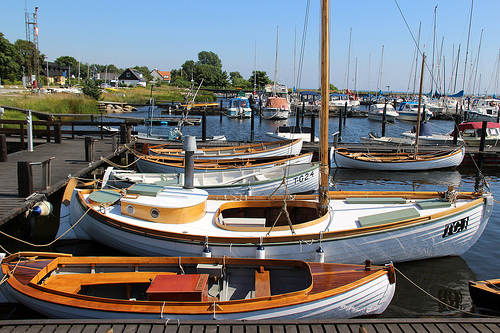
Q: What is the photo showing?
A: It is showing a harbor.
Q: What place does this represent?
A: It represents the harbor.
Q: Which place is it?
A: It is a harbor.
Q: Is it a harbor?
A: Yes, it is a harbor.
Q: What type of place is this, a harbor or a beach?
A: It is a harbor.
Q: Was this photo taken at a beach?
A: No, the picture was taken in a harbor.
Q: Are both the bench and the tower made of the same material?
A: No, the bench is made of wood and the tower is made of metal.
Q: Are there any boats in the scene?
A: Yes, there is a boat.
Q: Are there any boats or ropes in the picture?
A: Yes, there is a boat.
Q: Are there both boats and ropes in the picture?
A: Yes, there are both a boat and a rope.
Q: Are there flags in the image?
A: No, there are no flags.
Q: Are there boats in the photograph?
A: Yes, there is a boat.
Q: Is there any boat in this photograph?
A: Yes, there is a boat.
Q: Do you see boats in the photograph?
A: Yes, there is a boat.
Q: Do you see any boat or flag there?
A: Yes, there is a boat.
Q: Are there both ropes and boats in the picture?
A: Yes, there are both a boat and a rope.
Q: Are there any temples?
A: No, there are no temples.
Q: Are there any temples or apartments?
A: No, there are no temples or apartments.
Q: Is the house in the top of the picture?
A: Yes, the house is in the top of the image.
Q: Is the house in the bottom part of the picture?
A: No, the house is in the top of the image.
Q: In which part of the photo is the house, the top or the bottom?
A: The house is in the top of the image.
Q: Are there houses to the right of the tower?
A: Yes, there is a house to the right of the tower.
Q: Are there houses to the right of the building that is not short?
A: Yes, there is a house to the right of the tower.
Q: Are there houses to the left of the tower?
A: No, the house is to the right of the tower.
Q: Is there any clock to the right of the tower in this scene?
A: No, there is a house to the right of the tower.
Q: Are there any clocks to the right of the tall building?
A: No, there is a house to the right of the tower.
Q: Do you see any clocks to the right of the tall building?
A: No, there is a house to the right of the tower.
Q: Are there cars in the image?
A: No, there are no cars.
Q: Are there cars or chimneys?
A: No, there are no cars or chimneys.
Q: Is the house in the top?
A: Yes, the house is in the top of the image.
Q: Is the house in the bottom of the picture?
A: No, the house is in the top of the image.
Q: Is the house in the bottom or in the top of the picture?
A: The house is in the top of the image.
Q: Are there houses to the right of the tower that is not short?
A: Yes, there is a house to the right of the tower.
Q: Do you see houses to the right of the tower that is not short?
A: Yes, there is a house to the right of the tower.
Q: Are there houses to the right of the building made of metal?
A: Yes, there is a house to the right of the tower.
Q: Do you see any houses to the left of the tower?
A: No, the house is to the right of the tower.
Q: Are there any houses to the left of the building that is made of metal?
A: No, the house is to the right of the tower.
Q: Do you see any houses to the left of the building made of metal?
A: No, the house is to the right of the tower.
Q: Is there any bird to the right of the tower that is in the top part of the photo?
A: No, there is a house to the right of the tower.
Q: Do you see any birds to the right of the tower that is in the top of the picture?
A: No, there is a house to the right of the tower.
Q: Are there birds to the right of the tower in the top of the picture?
A: No, there is a house to the right of the tower.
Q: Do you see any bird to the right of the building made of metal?
A: No, there is a house to the right of the tower.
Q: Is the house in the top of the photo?
A: Yes, the house is in the top of the image.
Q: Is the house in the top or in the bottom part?
A: The house is in the top of the image.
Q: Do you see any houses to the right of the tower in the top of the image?
A: Yes, there is a house to the right of the tower.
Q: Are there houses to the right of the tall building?
A: Yes, there is a house to the right of the tower.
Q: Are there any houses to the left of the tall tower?
A: No, the house is to the right of the tower.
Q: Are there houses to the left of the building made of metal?
A: No, the house is to the right of the tower.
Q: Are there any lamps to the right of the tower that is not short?
A: No, there is a house to the right of the tower.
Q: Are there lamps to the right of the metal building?
A: No, there is a house to the right of the tower.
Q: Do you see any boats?
A: Yes, there is a boat.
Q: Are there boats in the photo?
A: Yes, there is a boat.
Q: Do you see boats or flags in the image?
A: Yes, there is a boat.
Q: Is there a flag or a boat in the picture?
A: Yes, there is a boat.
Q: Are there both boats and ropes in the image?
A: Yes, there are both a boat and a rope.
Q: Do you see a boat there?
A: Yes, there is a boat.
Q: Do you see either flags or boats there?
A: Yes, there is a boat.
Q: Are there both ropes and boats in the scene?
A: Yes, there are both a boat and a rope.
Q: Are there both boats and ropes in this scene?
A: Yes, there are both a boat and a rope.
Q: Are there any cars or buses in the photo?
A: No, there are no cars or buses.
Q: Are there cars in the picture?
A: No, there are no cars.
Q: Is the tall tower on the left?
A: Yes, the tower is on the left of the image.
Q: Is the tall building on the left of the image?
A: Yes, the tower is on the left of the image.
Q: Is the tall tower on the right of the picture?
A: No, the tower is on the left of the image.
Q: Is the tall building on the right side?
A: No, the tower is on the left of the image.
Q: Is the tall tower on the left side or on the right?
A: The tower is on the left of the image.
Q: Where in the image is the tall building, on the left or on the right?
A: The tower is on the left of the image.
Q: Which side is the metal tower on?
A: The tower is on the left of the image.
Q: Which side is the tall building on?
A: The tower is on the left of the image.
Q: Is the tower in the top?
A: Yes, the tower is in the top of the image.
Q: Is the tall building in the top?
A: Yes, the tower is in the top of the image.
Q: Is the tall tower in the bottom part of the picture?
A: No, the tower is in the top of the image.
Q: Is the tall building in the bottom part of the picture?
A: No, the tower is in the top of the image.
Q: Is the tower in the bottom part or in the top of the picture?
A: The tower is in the top of the image.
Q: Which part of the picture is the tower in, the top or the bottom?
A: The tower is in the top of the image.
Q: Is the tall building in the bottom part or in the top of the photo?
A: The tower is in the top of the image.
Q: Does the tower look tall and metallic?
A: Yes, the tower is tall and metallic.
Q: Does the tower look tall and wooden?
A: No, the tower is tall but metallic.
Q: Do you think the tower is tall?
A: Yes, the tower is tall.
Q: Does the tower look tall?
A: Yes, the tower is tall.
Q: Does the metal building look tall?
A: Yes, the tower is tall.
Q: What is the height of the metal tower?
A: The tower is tall.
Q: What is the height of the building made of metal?
A: The tower is tall.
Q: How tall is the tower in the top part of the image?
A: The tower is tall.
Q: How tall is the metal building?
A: The tower is tall.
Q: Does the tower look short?
A: No, the tower is tall.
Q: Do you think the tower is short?
A: No, the tower is tall.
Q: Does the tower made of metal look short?
A: No, the tower is tall.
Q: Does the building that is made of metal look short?
A: No, the tower is tall.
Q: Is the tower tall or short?
A: The tower is tall.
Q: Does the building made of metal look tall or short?
A: The tower is tall.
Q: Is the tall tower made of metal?
A: Yes, the tower is made of metal.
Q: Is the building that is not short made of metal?
A: Yes, the tower is made of metal.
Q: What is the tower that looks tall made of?
A: The tower is made of metal.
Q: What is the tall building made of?
A: The tower is made of metal.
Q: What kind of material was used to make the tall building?
A: The tower is made of metal.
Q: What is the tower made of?
A: The tower is made of metal.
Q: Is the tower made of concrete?
A: No, the tower is made of metal.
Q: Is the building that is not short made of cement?
A: No, the tower is made of metal.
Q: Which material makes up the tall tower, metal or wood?
A: The tower is made of metal.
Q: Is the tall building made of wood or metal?
A: The tower is made of metal.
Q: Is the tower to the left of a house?
A: Yes, the tower is to the left of a house.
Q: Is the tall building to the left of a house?
A: Yes, the tower is to the left of a house.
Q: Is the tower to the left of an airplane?
A: No, the tower is to the left of a house.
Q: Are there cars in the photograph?
A: No, there are no cars.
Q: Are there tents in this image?
A: No, there are no tents.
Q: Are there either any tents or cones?
A: No, there are no tents or cones.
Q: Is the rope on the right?
A: Yes, the rope is on the right of the image.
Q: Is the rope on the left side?
A: No, the rope is on the right of the image.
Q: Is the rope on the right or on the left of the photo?
A: The rope is on the right of the image.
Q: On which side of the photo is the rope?
A: The rope is on the right of the image.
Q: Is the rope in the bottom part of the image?
A: Yes, the rope is in the bottom of the image.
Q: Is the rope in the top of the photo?
A: No, the rope is in the bottom of the image.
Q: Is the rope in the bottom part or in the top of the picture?
A: The rope is in the bottom of the image.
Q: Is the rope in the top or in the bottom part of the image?
A: The rope is in the bottom of the image.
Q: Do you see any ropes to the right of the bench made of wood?
A: Yes, there is a rope to the right of the bench.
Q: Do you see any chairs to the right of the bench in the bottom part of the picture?
A: No, there is a rope to the right of the bench.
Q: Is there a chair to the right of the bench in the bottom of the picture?
A: No, there is a rope to the right of the bench.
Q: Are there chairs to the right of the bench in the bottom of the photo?
A: No, there is a rope to the right of the bench.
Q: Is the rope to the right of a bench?
A: Yes, the rope is to the right of a bench.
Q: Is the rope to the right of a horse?
A: No, the rope is to the right of a bench.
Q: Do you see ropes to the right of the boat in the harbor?
A: Yes, there is a rope to the right of the boat.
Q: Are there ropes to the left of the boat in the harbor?
A: No, the rope is to the right of the boat.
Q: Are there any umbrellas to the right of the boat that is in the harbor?
A: No, there is a rope to the right of the boat.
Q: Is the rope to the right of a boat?
A: Yes, the rope is to the right of a boat.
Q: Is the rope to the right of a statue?
A: No, the rope is to the right of a boat.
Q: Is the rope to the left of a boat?
A: No, the rope is to the right of a boat.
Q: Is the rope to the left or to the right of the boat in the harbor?
A: The rope is to the right of the boat.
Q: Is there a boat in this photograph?
A: Yes, there is a boat.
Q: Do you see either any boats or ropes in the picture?
A: Yes, there is a boat.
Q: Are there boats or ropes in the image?
A: Yes, there is a boat.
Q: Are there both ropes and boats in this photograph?
A: Yes, there are both a boat and a rope.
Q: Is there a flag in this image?
A: No, there are no flags.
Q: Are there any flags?
A: No, there are no flags.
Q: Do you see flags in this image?
A: No, there are no flags.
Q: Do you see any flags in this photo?
A: No, there are no flags.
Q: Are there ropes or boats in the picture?
A: Yes, there is a boat.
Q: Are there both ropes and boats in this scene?
A: Yes, there are both a boat and a rope.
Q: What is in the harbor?
A: The boat is in the harbor.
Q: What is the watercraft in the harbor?
A: The watercraft is a boat.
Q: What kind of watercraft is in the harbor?
A: The watercraft is a boat.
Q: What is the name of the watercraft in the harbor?
A: The watercraft is a boat.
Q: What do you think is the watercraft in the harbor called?
A: The watercraft is a boat.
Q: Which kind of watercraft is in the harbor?
A: The watercraft is a boat.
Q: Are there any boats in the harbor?
A: Yes, there is a boat in the harbor.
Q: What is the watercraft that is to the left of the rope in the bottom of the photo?
A: The watercraft is a boat.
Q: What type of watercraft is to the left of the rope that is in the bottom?
A: The watercraft is a boat.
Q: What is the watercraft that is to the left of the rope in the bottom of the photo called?
A: The watercraft is a boat.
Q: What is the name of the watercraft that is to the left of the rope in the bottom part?
A: The watercraft is a boat.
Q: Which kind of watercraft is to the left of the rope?
A: The watercraft is a boat.